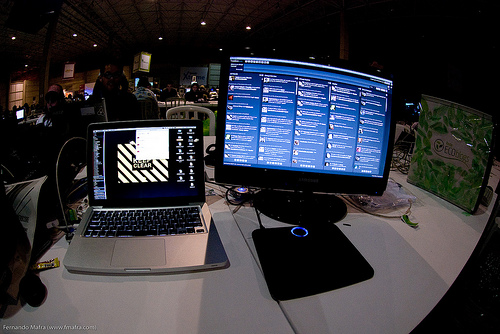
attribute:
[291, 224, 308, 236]
part — blue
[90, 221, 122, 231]
key — black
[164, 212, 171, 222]
key — black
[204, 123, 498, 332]
table — white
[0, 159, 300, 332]
table — white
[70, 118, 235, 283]
laptop — silver, black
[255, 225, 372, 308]
touch pad — accesory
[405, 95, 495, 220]
box — white, green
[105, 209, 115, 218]
key — black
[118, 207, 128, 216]
key — black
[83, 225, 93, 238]
key — black